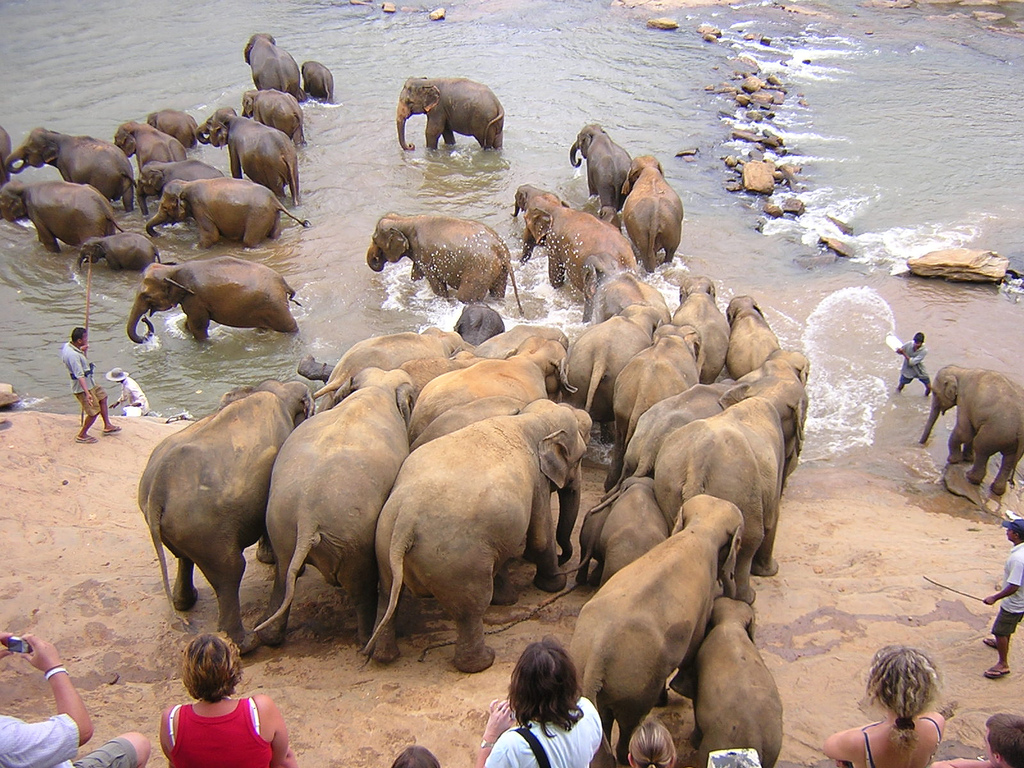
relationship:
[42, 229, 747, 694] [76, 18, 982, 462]
elephants by stream